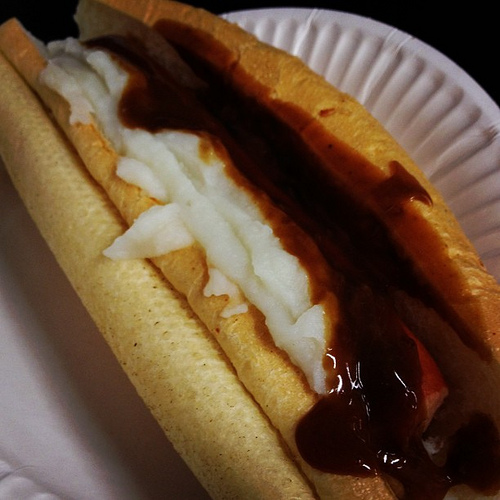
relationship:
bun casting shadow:
[0, 0, 500, 500] [54, 350, 133, 457]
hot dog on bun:
[403, 324, 449, 434] [1, 2, 498, 487]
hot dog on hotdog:
[403, 324, 449, 434] [3, 4, 496, 498]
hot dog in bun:
[403, 324, 449, 434] [1, 2, 498, 487]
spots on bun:
[0, 61, 313, 499] [0, 13, 420, 495]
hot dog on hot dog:
[403, 324, 449, 434] [2, 3, 494, 493]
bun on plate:
[1, 2, 498, 487] [386, 31, 461, 78]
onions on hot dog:
[41, 36, 326, 395] [2, 3, 494, 493]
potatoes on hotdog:
[198, 117, 364, 293] [36, 22, 476, 385]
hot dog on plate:
[2, 3, 494, 493] [1, 7, 497, 498]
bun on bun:
[0, 0, 500, 500] [11, 57, 498, 474]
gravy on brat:
[323, 196, 408, 435] [389, 325, 462, 453]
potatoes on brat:
[131, 122, 374, 337] [389, 325, 462, 453]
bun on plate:
[0, 0, 500, 500] [229, 7, 498, 262]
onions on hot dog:
[155, 158, 236, 261] [2, 3, 494, 493]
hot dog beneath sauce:
[403, 324, 449, 434] [115, 31, 433, 491]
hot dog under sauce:
[403, 324, 449, 434] [41, 10, 498, 498]